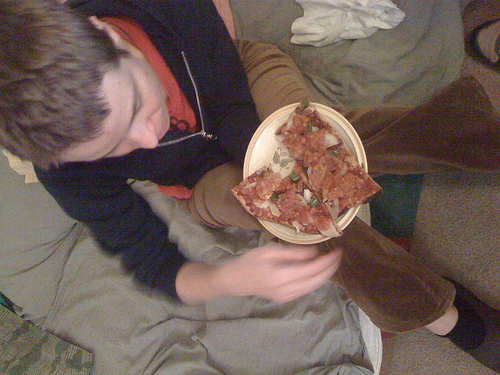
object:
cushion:
[0, 304, 92, 374]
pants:
[179, 39, 499, 333]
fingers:
[264, 245, 342, 305]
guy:
[0, 0, 500, 370]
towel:
[289, 0, 407, 47]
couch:
[2, 0, 500, 375]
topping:
[289, 172, 301, 183]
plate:
[242, 102, 369, 245]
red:
[166, 93, 193, 114]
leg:
[341, 232, 460, 337]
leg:
[361, 105, 497, 178]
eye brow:
[130, 75, 138, 125]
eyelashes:
[138, 86, 143, 111]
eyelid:
[135, 92, 140, 109]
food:
[231, 100, 382, 239]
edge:
[241, 101, 302, 181]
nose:
[130, 119, 158, 150]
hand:
[233, 241, 342, 305]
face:
[64, 50, 169, 163]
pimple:
[141, 70, 151, 76]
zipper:
[158, 52, 218, 148]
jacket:
[32, 0, 261, 307]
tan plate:
[241, 101, 368, 245]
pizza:
[230, 99, 382, 240]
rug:
[389, 0, 500, 374]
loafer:
[440, 277, 499, 373]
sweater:
[34, 0, 261, 308]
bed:
[0, 0, 500, 375]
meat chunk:
[276, 192, 310, 224]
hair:
[0, 0, 129, 172]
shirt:
[91, 14, 198, 200]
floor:
[424, 179, 482, 255]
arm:
[46, 182, 221, 300]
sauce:
[354, 177, 371, 197]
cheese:
[325, 133, 339, 146]